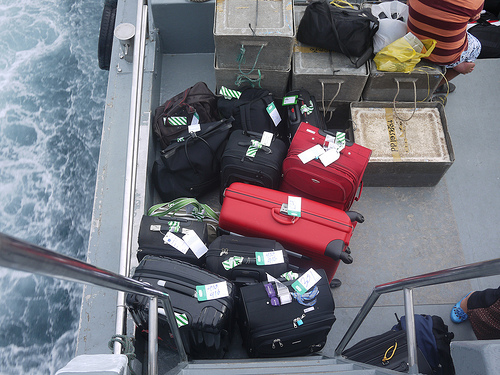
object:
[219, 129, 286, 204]
luggage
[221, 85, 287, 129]
luggage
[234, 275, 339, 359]
luggage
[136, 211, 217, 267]
luggage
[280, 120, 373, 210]
luggage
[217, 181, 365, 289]
luggage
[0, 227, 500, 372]
stairs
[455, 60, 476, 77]
foot of girl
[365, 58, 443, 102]
luggage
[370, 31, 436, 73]
sheer bag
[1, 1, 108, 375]
water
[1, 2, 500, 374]
boat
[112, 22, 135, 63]
cup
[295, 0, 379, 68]
bag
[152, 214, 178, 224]
rope handle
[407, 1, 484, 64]
shirt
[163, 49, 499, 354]
part of floor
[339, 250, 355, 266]
wheel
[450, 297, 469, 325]
shoe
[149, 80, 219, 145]
luggage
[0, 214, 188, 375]
railing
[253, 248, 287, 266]
luggage tag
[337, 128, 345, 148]
tag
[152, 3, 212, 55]
container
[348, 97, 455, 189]
box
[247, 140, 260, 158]
flag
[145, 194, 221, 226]
bag